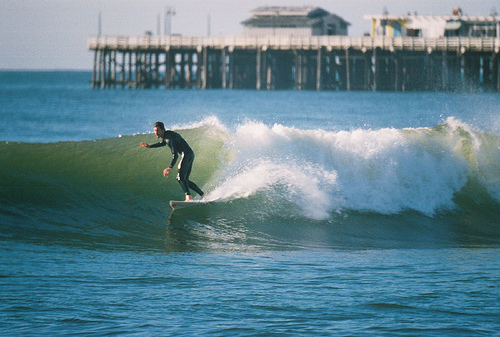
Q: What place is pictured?
A: It is an ocean.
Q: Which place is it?
A: It is an ocean.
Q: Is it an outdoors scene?
A: Yes, it is outdoors.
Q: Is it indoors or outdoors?
A: It is outdoors.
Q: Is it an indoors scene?
A: No, it is outdoors.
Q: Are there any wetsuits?
A: Yes, there is a wetsuit.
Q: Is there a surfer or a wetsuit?
A: Yes, there is a wetsuit.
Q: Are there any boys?
A: No, there are no boys.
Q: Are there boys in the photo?
A: No, there are no boys.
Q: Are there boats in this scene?
A: No, there are no boats.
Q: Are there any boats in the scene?
A: No, there are no boats.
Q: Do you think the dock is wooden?
A: Yes, the dock is wooden.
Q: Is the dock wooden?
A: Yes, the dock is wooden.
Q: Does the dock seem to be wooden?
A: Yes, the dock is wooden.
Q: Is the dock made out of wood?
A: Yes, the dock is made of wood.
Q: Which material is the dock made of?
A: The dock is made of wood.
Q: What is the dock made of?
A: The dock is made of wood.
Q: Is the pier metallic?
A: No, the pier is wooden.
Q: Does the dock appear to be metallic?
A: No, the dock is wooden.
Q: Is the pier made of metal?
A: No, the pier is made of wood.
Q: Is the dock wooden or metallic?
A: The dock is wooden.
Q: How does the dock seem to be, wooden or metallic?
A: The dock is wooden.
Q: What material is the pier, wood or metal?
A: The pier is made of wood.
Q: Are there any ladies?
A: No, there are no ladies.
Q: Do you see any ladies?
A: No, there are no ladies.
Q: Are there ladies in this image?
A: No, there are no ladies.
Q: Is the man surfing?
A: Yes, the man is surfing.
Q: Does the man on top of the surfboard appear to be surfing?
A: Yes, the man is surfing.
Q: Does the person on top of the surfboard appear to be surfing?
A: Yes, the man is surfing.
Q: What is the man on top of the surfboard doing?
A: The man is surfing.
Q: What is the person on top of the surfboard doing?
A: The man is surfing.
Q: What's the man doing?
A: The man is surfing.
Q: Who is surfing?
A: The man is surfing.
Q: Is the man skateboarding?
A: No, the man is surfing.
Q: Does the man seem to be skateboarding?
A: No, the man is surfing.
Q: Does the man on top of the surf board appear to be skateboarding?
A: No, the man is surfing.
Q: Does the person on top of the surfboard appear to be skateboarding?
A: No, the man is surfing.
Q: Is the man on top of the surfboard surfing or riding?
A: The man is surfing.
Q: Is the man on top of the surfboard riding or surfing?
A: The man is surfing.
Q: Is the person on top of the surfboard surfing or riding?
A: The man is surfing.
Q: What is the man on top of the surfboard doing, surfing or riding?
A: The man is surfing.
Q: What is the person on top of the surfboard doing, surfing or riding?
A: The man is surfing.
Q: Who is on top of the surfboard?
A: The man is on top of the surfboard.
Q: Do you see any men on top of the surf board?
A: Yes, there is a man on top of the surf board.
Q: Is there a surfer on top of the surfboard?
A: No, there is a man on top of the surfboard.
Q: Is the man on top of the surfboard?
A: Yes, the man is on top of the surfboard.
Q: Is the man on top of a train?
A: No, the man is on top of the surfboard.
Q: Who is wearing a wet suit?
A: The man is wearing a wet suit.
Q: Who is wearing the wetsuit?
A: The man is wearing a wet suit.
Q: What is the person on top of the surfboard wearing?
A: The man is wearing a wetsuit.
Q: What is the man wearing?
A: The man is wearing a wetsuit.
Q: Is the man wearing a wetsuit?
A: Yes, the man is wearing a wetsuit.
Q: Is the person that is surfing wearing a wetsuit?
A: Yes, the man is wearing a wetsuit.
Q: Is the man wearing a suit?
A: No, the man is wearing a wetsuit.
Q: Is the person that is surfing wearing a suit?
A: No, the man is wearing a wetsuit.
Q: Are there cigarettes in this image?
A: No, there are no cigarettes.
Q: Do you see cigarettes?
A: No, there are no cigarettes.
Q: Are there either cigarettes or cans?
A: No, there are no cigarettes or cans.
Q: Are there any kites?
A: No, there are no kites.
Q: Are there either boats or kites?
A: No, there are no kites or boats.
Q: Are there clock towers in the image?
A: No, there are no clock towers.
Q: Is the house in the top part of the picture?
A: Yes, the house is in the top of the image.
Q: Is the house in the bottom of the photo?
A: No, the house is in the top of the image.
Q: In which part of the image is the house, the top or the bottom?
A: The house is in the top of the image.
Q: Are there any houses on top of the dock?
A: Yes, there is a house on top of the dock.